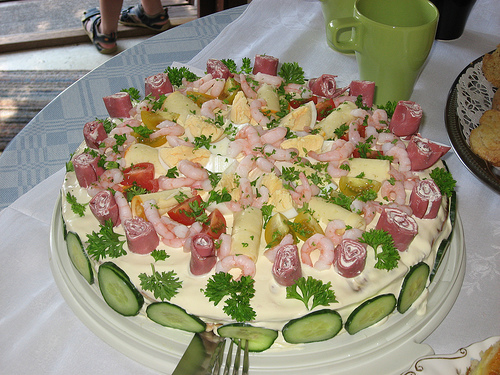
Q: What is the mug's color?
A: Green.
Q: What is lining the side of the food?
A: Cucumbers.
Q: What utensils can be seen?
A: A fork and knife.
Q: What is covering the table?
A: A white cloth.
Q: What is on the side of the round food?
A: Veggie.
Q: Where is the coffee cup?
A: Behind the platter.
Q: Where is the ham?
A: On the platter.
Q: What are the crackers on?
A: A doily.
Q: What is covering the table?
A: A table cloth.